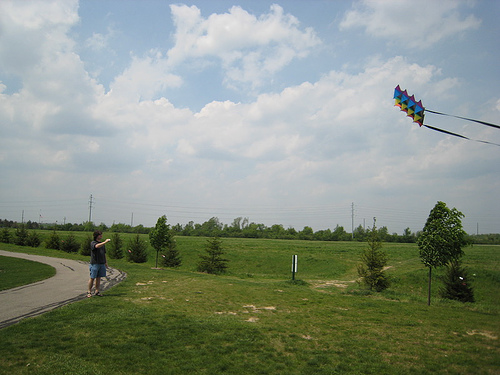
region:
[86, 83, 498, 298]
a man flying a kite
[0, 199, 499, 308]
row of various trees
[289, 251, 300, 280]
a sign posted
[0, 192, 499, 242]
electrical power lines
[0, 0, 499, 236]
a cloudy sky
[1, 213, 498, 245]
a tree line in the background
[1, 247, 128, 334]
a paved walkway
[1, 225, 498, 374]
large green prarie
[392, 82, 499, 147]
a multicolored kite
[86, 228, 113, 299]
a man in a t-shirt and shorts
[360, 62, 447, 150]
the kite is flying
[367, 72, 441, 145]
the kite is colorful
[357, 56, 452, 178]
the kite is colorful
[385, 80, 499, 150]
Colorful kite flying through the sky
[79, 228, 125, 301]
Person wearing light blue cargo shorts on their legs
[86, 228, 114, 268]
Person wearing a black colored t shirt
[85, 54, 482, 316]
Person on the ground using a string to fly a kite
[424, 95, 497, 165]
Twin tails of a kite leading off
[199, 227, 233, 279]
Small pine tree with leaves forming clear layers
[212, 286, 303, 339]
Short light green grass with patches of visible dirt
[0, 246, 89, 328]
Gray asphalt road curving around a green grass patch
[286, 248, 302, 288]
White sign on a metal post facing the opposite direction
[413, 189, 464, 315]
Leaves of a tree forming a round circle on a thin trunk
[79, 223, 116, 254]
the head of a man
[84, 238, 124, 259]
the arm of a man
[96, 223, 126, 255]
the hand of a man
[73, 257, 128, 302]
the legs of a man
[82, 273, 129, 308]
the feet of a man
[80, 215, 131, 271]
a man wearing a shirt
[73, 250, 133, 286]
a man wearing shorts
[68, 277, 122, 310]
a man wearing shoes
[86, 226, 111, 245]
the hair of a man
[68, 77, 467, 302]
a man flying a kite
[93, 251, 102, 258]
man wearing blue shirt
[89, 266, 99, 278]
man wearing light blue shorts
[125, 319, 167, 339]
green grass in meadow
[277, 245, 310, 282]
back of sign in meadow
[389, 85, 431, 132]
color tricolor kite in sky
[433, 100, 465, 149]
string attached to kite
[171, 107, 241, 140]
white clouds in sky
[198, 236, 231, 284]
short pine tree in meadow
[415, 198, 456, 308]
tall pine tree in meadow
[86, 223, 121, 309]
man flying kite in meadow